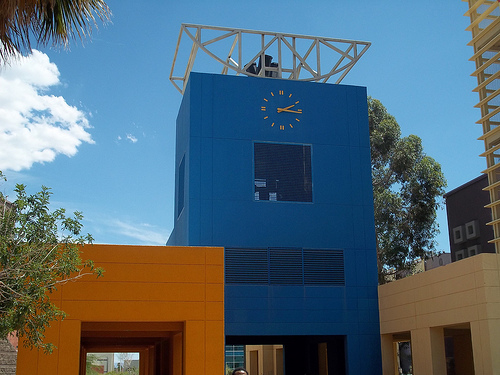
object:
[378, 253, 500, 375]
building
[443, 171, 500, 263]
building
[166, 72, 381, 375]
pillar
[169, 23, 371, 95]
antenna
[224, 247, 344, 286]
window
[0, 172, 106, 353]
tree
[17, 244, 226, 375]
building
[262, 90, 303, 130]
clock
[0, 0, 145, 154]
sky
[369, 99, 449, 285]
tree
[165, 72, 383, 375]
building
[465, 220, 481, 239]
window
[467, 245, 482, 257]
window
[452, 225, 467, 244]
window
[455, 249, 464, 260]
window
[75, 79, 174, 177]
sky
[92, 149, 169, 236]
sky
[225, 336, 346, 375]
gap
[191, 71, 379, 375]
wall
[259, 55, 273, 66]
head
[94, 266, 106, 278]
branches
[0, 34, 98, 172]
cloud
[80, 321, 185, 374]
breezeway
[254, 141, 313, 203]
window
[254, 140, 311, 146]
bad sentenc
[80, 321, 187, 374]
opening